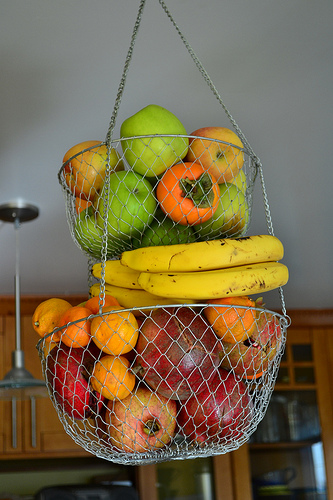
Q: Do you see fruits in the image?
A: Yes, there is a fruit.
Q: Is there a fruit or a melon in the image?
A: Yes, there is a fruit.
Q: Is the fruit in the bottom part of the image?
A: Yes, the fruit is in the bottom of the image.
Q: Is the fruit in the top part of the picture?
A: No, the fruit is in the bottom of the image.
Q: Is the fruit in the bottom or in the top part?
A: The fruit is in the bottom of the image.